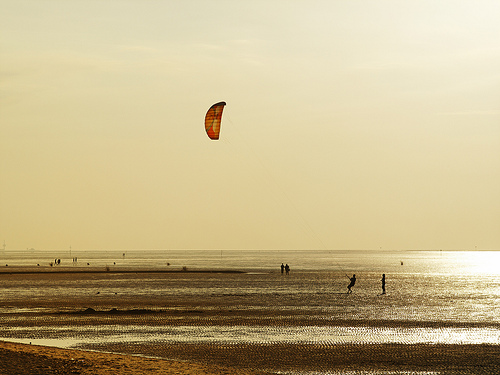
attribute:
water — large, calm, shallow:
[3, 252, 497, 373]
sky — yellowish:
[23, 85, 179, 227]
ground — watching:
[263, 102, 300, 139]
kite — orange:
[202, 95, 227, 145]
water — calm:
[232, 247, 391, 272]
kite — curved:
[201, 100, 226, 139]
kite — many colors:
[192, 94, 297, 157]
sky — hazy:
[1, 0, 499, 250]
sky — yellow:
[421, 178, 493, 241]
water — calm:
[175, 263, 277, 300]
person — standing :
[362, 272, 407, 346]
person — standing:
[360, 249, 421, 344]